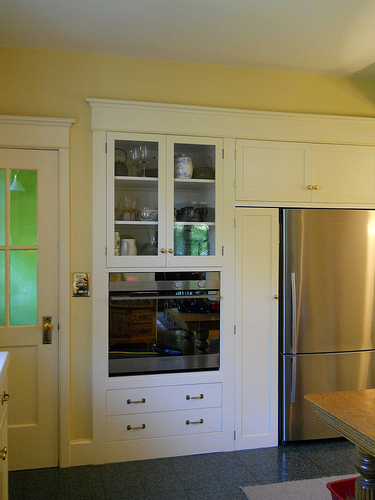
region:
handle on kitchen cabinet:
[314, 181, 320, 192]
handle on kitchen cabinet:
[308, 176, 312, 195]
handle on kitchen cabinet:
[168, 244, 173, 256]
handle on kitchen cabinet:
[157, 246, 165, 256]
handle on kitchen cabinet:
[272, 293, 279, 299]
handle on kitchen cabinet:
[1, 446, 7, 454]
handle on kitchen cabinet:
[1, 451, 6, 460]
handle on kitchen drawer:
[126, 395, 149, 407]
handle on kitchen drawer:
[185, 390, 204, 400]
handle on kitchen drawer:
[126, 422, 147, 433]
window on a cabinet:
[113, 139, 156, 179]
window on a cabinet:
[174, 141, 216, 259]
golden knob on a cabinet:
[159, 247, 164, 254]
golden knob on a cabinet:
[168, 246, 173, 252]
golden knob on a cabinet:
[307, 184, 312, 190]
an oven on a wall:
[107, 271, 222, 374]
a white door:
[0, 147, 61, 470]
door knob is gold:
[41, 314, 50, 345]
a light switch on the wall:
[72, 271, 89, 297]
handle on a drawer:
[126, 399, 144, 406]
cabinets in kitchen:
[114, 142, 218, 261]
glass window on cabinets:
[116, 142, 154, 262]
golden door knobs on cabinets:
[159, 244, 175, 256]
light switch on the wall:
[74, 269, 92, 298]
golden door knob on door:
[39, 319, 58, 343]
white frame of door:
[0, 117, 79, 147]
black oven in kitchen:
[102, 268, 220, 383]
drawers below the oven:
[78, 384, 233, 450]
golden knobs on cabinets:
[301, 184, 321, 194]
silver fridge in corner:
[288, 206, 372, 417]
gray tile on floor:
[65, 469, 92, 485]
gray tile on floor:
[99, 460, 129, 475]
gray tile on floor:
[111, 479, 145, 488]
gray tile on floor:
[142, 461, 170, 478]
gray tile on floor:
[150, 477, 187, 487]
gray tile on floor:
[183, 462, 206, 481]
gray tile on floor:
[198, 486, 215, 497]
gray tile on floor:
[215, 451, 250, 476]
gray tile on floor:
[252, 448, 272, 468]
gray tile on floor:
[274, 462, 304, 473]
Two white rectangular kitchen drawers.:
[99, 374, 222, 446]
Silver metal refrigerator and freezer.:
[273, 200, 371, 441]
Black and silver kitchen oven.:
[106, 272, 220, 375]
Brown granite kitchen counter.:
[301, 383, 372, 457]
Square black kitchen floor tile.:
[135, 451, 241, 499]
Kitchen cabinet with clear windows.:
[110, 140, 223, 264]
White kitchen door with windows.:
[2, 127, 68, 463]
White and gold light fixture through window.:
[2, 171, 30, 200]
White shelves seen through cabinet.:
[111, 138, 221, 261]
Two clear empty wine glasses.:
[128, 144, 152, 177]